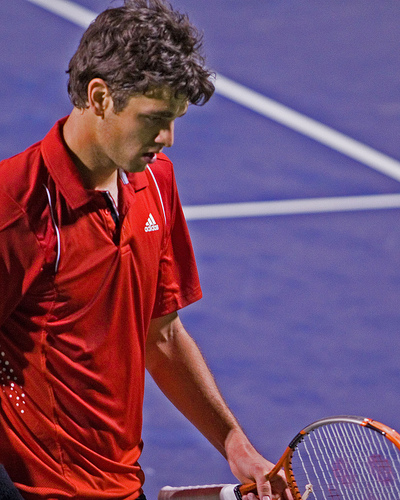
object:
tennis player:
[2, 0, 293, 499]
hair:
[67, 4, 217, 109]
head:
[62, 14, 203, 174]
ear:
[88, 75, 113, 126]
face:
[100, 95, 180, 174]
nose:
[152, 125, 175, 146]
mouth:
[139, 147, 164, 163]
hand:
[224, 436, 291, 499]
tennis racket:
[158, 409, 397, 500]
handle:
[159, 475, 243, 500]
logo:
[144, 212, 160, 233]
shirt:
[0, 110, 203, 500]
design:
[0, 347, 34, 414]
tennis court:
[1, 2, 400, 500]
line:
[37, 0, 400, 177]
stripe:
[39, 173, 67, 275]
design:
[330, 448, 393, 489]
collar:
[39, 116, 153, 211]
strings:
[295, 444, 318, 500]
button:
[104, 202, 113, 215]